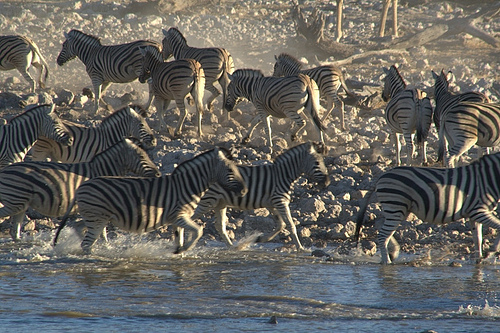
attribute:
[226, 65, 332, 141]
zebra — black, white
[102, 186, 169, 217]
strips — black and white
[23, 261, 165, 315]
water — calm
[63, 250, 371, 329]
water — small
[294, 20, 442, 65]
log — large, brown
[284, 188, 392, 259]
shore — rocky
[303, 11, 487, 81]
drift wood — giant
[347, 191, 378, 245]
tail — wet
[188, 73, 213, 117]
tail — white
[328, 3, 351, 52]
tree trunk — small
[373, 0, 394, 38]
tree trunk — small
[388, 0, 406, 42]
tree trunk — small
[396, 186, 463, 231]
zebra's belly — fat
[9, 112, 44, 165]
zebra's neck — thick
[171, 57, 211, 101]
rear end — large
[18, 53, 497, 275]
zebras — running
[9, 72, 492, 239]
zebras — walking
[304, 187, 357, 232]
rocks — facing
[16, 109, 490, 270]
zebras — standing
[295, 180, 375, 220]
rocks — grey